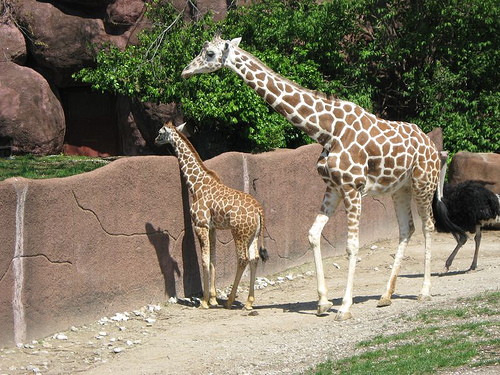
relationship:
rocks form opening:
[4, 2, 183, 146] [59, 83, 119, 157]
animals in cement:
[153, 29, 499, 320] [0, 126, 498, 345]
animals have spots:
[153, 29, 456, 320] [157, 35, 442, 260]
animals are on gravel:
[153, 29, 499, 320] [9, 227, 495, 374]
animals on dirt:
[153, 29, 499, 320] [6, 236, 498, 371]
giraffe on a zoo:
[183, 31, 444, 319] [5, 7, 498, 374]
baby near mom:
[153, 119, 268, 314] [183, 31, 444, 319]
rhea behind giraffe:
[438, 147, 500, 274] [183, 31, 444, 319]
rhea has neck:
[438, 147, 500, 274] [440, 163, 447, 201]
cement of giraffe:
[0, 126, 498, 345] [153, 29, 456, 320]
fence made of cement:
[3, 130, 499, 344] [6, 126, 498, 345]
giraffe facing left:
[183, 31, 444, 319] [6, 6, 230, 367]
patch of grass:
[0, 154, 100, 179] [1, 154, 98, 177]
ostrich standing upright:
[438, 147, 500, 274] [438, 148, 500, 278]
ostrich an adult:
[438, 147, 500, 274] [436, 151, 499, 280]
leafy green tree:
[73, 5, 496, 147] [73, 2, 499, 146]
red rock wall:
[62, 87, 116, 156] [3, 5, 222, 152]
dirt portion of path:
[6, 236, 498, 371] [7, 237, 500, 374]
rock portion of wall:
[4, 2, 183, 146] [3, 5, 222, 152]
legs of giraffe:
[305, 189, 364, 322] [183, 31, 444, 319]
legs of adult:
[305, 189, 364, 322] [178, 34, 442, 318]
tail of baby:
[257, 210, 274, 261] [153, 119, 268, 314]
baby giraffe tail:
[153, 119, 268, 314] [257, 210, 274, 261]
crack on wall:
[0, 180, 385, 279] [3, 130, 499, 344]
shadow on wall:
[141, 167, 206, 297] [3, 130, 499, 344]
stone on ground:
[452, 151, 499, 232] [7, 236, 490, 375]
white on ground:
[9, 279, 321, 372] [7, 236, 490, 375]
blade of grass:
[327, 296, 496, 374] [319, 307, 500, 372]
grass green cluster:
[319, 307, 500, 372] [328, 299, 497, 374]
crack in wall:
[0, 180, 385, 279] [3, 130, 499, 344]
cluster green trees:
[80, 2, 499, 147] [73, 2, 499, 146]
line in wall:
[13, 179, 38, 343] [3, 130, 499, 344]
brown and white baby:
[168, 138, 270, 265] [153, 119, 268, 314]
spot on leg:
[345, 190, 362, 241] [337, 193, 361, 319]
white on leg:
[347, 254, 353, 310] [337, 193, 361, 319]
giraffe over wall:
[183, 31, 444, 319] [3, 130, 499, 344]